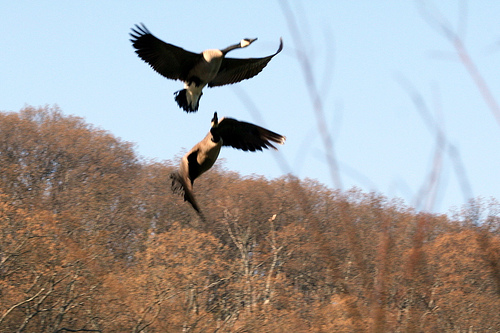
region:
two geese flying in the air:
[121, 22, 304, 241]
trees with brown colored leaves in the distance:
[1, 109, 498, 326]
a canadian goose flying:
[123, 23, 289, 117]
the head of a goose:
[227, 38, 257, 53]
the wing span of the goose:
[121, 22, 281, 86]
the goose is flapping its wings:
[164, 109, 289, 217]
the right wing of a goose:
[127, 16, 198, 86]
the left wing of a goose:
[210, 36, 282, 91]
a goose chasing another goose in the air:
[117, 16, 296, 231]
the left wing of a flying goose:
[212, 117, 292, 157]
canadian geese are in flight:
[13, 1, 388, 271]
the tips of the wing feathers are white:
[276, 128, 288, 152]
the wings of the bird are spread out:
[123, 18, 283, 85]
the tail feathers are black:
[165, 86, 207, 116]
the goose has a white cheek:
[235, 33, 262, 53]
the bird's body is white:
[179, 136, 217, 178]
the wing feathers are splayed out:
[123, 13, 165, 60]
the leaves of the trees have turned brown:
[1, 111, 498, 328]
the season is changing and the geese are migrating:
[13, 13, 489, 315]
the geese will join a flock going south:
[56, 6, 335, 223]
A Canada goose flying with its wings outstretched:
[121, 12, 288, 113]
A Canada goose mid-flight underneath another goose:
[164, 111, 286, 223]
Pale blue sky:
[0, 2, 495, 222]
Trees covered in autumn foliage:
[0, 105, 499, 332]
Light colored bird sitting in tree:
[260, 205, 276, 225]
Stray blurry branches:
[220, 0, 495, 320]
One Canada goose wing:
[120, 14, 197, 89]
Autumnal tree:
[210, 164, 292, 329]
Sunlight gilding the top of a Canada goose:
[162, 119, 210, 209]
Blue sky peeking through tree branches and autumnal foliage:
[38, 154, 59, 208]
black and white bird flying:
[122, 18, 298, 110]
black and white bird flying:
[180, 102, 288, 198]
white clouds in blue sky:
[22, 15, 62, 51]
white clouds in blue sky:
[17, 52, 67, 78]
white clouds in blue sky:
[67, 33, 100, 78]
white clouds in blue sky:
[299, 31, 329, 75]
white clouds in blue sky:
[343, 25, 391, 61]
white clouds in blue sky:
[452, 32, 478, 79]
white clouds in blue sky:
[305, 93, 344, 127]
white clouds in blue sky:
[379, 87, 432, 151]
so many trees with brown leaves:
[6, 108, 498, 332]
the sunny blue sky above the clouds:
[1, 0, 499, 217]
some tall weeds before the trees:
[261, 7, 497, 330]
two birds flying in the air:
[126, 18, 290, 227]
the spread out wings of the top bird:
[128, 19, 287, 88]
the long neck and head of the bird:
[226, 35, 256, 53]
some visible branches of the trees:
[236, 235, 279, 302]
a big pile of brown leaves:
[1, 104, 137, 166]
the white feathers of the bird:
[183, 80, 203, 105]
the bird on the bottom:
[169, 111, 290, 216]